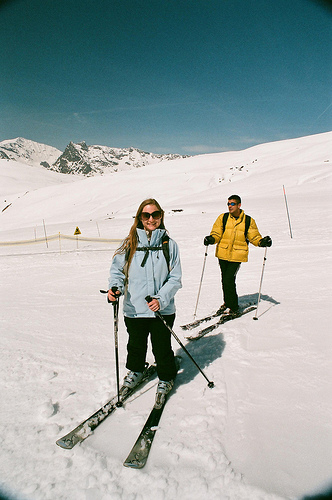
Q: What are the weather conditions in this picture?
A: It is cloudless.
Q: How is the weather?
A: It is cloudless.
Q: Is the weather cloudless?
A: Yes, it is cloudless.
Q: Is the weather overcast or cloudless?
A: It is cloudless.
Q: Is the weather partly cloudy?
A: No, it is cloudless.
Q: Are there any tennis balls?
A: No, there are no tennis balls.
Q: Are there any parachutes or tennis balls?
A: No, there are no tennis balls or parachutes.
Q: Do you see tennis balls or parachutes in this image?
A: No, there are no tennis balls or parachutes.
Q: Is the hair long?
A: Yes, the hair is long.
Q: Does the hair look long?
A: Yes, the hair is long.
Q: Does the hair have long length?
A: Yes, the hair is long.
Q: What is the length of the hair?
A: The hair is long.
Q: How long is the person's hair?
A: The hair is long.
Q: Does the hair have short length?
A: No, the hair is long.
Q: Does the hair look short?
A: No, the hair is long.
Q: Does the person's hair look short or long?
A: The hair is long.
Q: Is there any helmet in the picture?
A: No, there are no helmets.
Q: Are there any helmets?
A: No, there are no helmets.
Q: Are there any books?
A: No, there are no books.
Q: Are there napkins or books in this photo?
A: No, there are no books or napkins.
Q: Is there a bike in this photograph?
A: No, there are no bikes.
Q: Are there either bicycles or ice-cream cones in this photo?
A: No, there are no bicycles or ice-cream cones.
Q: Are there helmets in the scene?
A: No, there are no helmets.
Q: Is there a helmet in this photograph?
A: No, there are no helmets.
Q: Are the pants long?
A: Yes, the pants are long.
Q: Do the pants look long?
A: Yes, the pants are long.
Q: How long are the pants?
A: The pants are long.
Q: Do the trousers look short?
A: No, the trousers are long.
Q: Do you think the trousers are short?
A: No, the trousers are long.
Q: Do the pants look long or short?
A: The pants are long.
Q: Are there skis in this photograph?
A: Yes, there are skis.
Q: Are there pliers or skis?
A: Yes, there are skis.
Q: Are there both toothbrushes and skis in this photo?
A: No, there are skis but no toothbrushes.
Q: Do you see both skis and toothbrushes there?
A: No, there are skis but no toothbrushes.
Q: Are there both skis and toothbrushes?
A: No, there are skis but no toothbrushes.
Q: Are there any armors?
A: No, there are no armors.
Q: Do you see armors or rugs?
A: No, there are no armors or rugs.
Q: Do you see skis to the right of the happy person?
A: Yes, there are skis to the right of the person.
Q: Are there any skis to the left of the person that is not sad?
A: No, the skis are to the right of the person.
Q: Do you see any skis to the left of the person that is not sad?
A: No, the skis are to the right of the person.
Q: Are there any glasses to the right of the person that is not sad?
A: No, there are skis to the right of the person.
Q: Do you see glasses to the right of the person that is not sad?
A: No, there are skis to the right of the person.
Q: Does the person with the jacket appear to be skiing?
A: Yes, the person is skiing.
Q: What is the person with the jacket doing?
A: The person is skiing.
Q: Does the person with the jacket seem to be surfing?
A: No, the person is skiing.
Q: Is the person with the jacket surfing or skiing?
A: The person is skiing.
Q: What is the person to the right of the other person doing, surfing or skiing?
A: The person is skiing.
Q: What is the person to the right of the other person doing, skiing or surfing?
A: The person is skiing.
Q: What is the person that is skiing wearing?
A: The person is wearing a jacket.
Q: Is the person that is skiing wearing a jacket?
A: Yes, the person is wearing a jacket.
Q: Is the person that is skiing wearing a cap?
A: No, the person is wearing a jacket.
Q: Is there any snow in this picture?
A: Yes, there is snow.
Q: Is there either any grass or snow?
A: Yes, there is snow.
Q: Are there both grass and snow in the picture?
A: No, there is snow but no grass.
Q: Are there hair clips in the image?
A: No, there are no hair clips.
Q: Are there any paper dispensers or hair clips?
A: No, there are no hair clips or paper dispensers.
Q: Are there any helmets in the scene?
A: No, there are no helmets.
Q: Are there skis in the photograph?
A: Yes, there are skis.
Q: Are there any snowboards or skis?
A: Yes, there are skis.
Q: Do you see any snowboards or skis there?
A: Yes, there are skis.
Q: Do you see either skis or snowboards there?
A: Yes, there are skis.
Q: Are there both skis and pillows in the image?
A: No, there are skis but no pillows.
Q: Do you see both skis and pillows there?
A: No, there are skis but no pillows.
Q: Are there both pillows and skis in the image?
A: No, there are skis but no pillows.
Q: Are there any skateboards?
A: No, there are no skateboards.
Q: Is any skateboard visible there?
A: No, there are no skateboards.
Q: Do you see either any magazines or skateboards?
A: No, there are no skateboards or magazines.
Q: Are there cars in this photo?
A: No, there are no cars.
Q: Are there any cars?
A: No, there are no cars.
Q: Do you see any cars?
A: No, there are no cars.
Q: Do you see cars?
A: No, there are no cars.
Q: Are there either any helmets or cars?
A: No, there are no cars or helmets.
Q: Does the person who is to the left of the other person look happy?
A: Yes, the person is happy.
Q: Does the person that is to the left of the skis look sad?
A: No, the person is happy.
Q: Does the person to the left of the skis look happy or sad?
A: The person is happy.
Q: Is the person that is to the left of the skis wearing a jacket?
A: Yes, the person is wearing a jacket.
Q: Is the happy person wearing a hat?
A: No, the person is wearing a jacket.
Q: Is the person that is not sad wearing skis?
A: Yes, the person is wearing skis.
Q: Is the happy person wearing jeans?
A: No, the person is wearing skis.